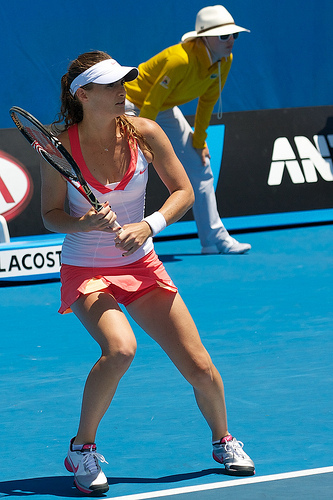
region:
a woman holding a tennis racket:
[28, 37, 277, 495]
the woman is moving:
[15, 17, 263, 473]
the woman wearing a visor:
[44, 57, 145, 114]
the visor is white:
[40, 47, 138, 96]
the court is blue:
[223, 275, 317, 372]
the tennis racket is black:
[2, 99, 119, 236]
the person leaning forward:
[102, 1, 277, 246]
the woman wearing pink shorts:
[26, 42, 252, 477]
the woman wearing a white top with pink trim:
[34, 103, 163, 267]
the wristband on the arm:
[121, 199, 173, 248]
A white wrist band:
[138, 207, 173, 235]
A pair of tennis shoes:
[50, 430, 253, 499]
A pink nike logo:
[68, 454, 83, 473]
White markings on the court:
[176, 470, 332, 499]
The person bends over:
[117, 3, 260, 258]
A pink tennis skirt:
[53, 248, 203, 326]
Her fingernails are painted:
[104, 199, 124, 231]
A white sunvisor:
[54, 43, 138, 88]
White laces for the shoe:
[81, 443, 107, 477]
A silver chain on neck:
[83, 120, 120, 159]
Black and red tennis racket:
[0, 102, 161, 249]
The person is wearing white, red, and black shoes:
[36, 425, 261, 493]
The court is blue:
[9, 220, 324, 492]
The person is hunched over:
[127, 5, 266, 143]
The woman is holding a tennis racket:
[11, 34, 214, 349]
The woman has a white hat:
[23, 43, 153, 138]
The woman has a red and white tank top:
[25, 26, 199, 294]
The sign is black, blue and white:
[178, 96, 328, 217]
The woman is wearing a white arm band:
[135, 191, 181, 245]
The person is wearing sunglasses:
[175, 3, 259, 93]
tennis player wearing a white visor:
[55, 51, 162, 113]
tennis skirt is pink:
[43, 232, 243, 327]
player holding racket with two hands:
[37, 107, 168, 266]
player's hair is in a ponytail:
[49, 57, 88, 138]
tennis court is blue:
[216, 286, 287, 387]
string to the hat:
[195, 29, 251, 117]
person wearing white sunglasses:
[197, 19, 268, 52]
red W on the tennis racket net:
[19, 121, 69, 165]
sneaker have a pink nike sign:
[66, 449, 84, 485]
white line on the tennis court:
[259, 471, 321, 488]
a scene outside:
[17, 14, 278, 488]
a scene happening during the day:
[21, 11, 320, 454]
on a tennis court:
[11, 9, 331, 434]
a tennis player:
[25, 45, 265, 498]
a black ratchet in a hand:
[4, 96, 167, 271]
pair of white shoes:
[46, 422, 275, 496]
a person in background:
[129, 9, 303, 257]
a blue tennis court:
[0, 231, 316, 498]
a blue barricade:
[9, 2, 315, 131]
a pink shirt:
[52, 249, 184, 329]